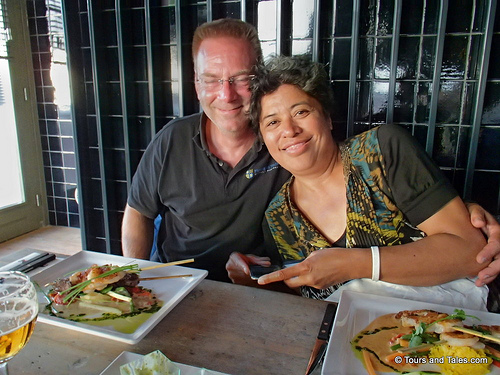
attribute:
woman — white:
[246, 54, 477, 301]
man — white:
[113, 17, 259, 277]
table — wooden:
[200, 304, 298, 356]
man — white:
[97, 14, 259, 282]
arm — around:
[459, 160, 495, 281]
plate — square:
[20, 235, 209, 351]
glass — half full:
[2, 264, 39, 373]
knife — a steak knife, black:
[307, 299, 345, 372]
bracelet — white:
[364, 240, 385, 283]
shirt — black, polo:
[126, 105, 293, 291]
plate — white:
[310, 286, 497, 372]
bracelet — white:
[368, 244, 383, 284]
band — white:
[368, 243, 382, 282]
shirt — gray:
[122, 110, 291, 275]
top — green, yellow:
[252, 120, 462, 294]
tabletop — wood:
[13, 249, 330, 371]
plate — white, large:
[27, 245, 212, 345]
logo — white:
[244, 166, 254, 178]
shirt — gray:
[125, 114, 301, 294]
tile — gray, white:
[27, 4, 78, 227]